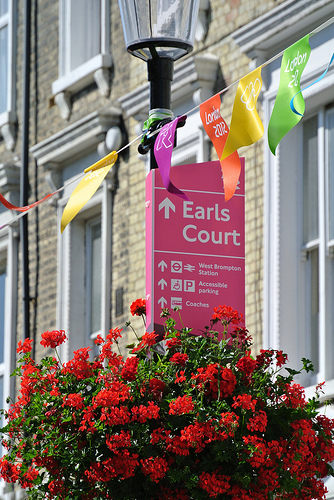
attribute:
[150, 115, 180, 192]
banner — triangular, purple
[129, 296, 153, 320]
flower — red, beautiful, numerous, sunny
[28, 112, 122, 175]
cornice — cement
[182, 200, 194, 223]
letter — white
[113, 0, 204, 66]
lamp — street, off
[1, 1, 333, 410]
building — yellow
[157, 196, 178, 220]
arrow — pointing, up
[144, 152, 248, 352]
sign — purple, pink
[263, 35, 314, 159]
pennant — green, multicolored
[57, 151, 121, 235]
flag — yellow, triangular, orange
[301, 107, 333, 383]
window — white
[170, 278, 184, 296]
logo — white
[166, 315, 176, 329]
leaf — green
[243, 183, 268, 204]
brick — tan